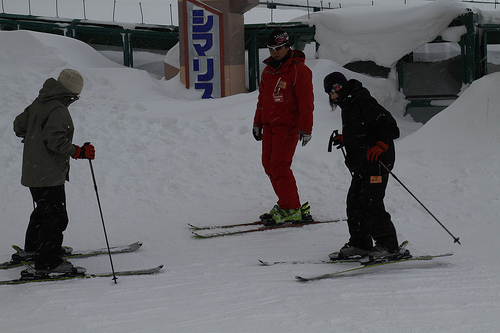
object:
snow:
[0, 0, 500, 332]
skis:
[257, 252, 456, 282]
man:
[249, 25, 316, 228]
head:
[267, 29, 291, 61]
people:
[10, 28, 416, 281]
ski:
[186, 210, 366, 240]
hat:
[266, 25, 291, 50]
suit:
[250, 51, 316, 207]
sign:
[174, 3, 247, 102]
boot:
[259, 200, 316, 228]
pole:
[366, 156, 467, 247]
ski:
[0, 238, 163, 287]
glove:
[299, 134, 313, 147]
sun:
[267, 40, 287, 55]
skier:
[10, 68, 97, 279]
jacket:
[12, 77, 78, 189]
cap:
[322, 71, 347, 94]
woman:
[322, 68, 414, 265]